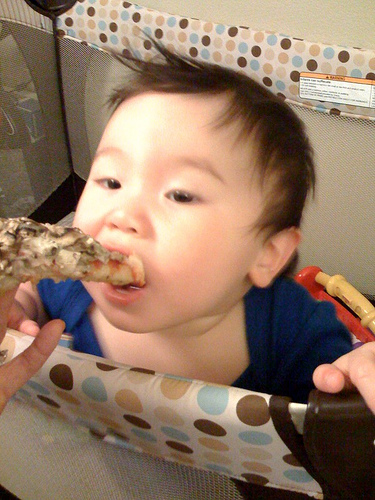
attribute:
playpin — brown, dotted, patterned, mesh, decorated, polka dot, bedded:
[2, 2, 374, 499]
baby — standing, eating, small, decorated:
[3, 28, 373, 412]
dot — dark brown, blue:
[307, 57, 317, 71]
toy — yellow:
[295, 266, 374, 346]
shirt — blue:
[41, 275, 352, 405]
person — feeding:
[2, 278, 67, 408]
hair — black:
[102, 27, 317, 229]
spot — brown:
[336, 50, 350, 62]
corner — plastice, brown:
[27, 0, 77, 17]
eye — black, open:
[165, 190, 205, 202]